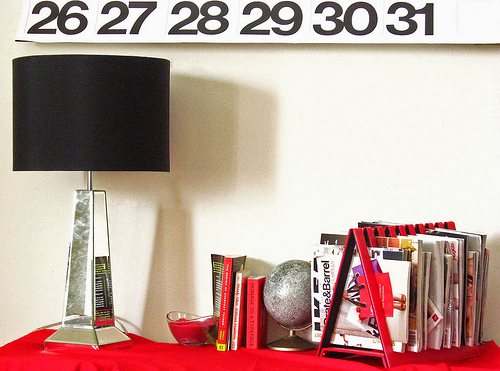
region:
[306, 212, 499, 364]
a rack full of catalogs/magazines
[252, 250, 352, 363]
a globe is in the photo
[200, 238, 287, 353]
books are on the table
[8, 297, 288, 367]
the cloth over the table is red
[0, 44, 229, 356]
the base of the lamp has a reflective surface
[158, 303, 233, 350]
a red candle sits there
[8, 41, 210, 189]
the lamp shade is black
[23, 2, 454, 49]
the numbers 26 thru 31 are at the top of the photo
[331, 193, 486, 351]
the magazine rack is red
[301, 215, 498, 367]
the magazine rack is shaped like a triangle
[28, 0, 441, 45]
numbers on bottom of poster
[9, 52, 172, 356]
black and clear lamp on table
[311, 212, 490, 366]
magazines in a red rack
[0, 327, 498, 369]
red cloth on table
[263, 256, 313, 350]
small globe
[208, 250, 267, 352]
three standing books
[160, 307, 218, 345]
clear bowl with red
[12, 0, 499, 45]
bottom section of a calender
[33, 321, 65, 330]
part of the lamps cord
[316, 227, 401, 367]
triangle shaped end of rack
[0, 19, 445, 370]
a lamp on a table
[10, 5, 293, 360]
lamp with a black shade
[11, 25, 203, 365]
a lamp on a red table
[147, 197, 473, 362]
books on a table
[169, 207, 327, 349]
books standing up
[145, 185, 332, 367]
books in between two statues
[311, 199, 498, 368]
magazines on a rack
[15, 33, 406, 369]
books on a table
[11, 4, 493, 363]
lamp and books on table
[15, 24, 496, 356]
lamp books and magazines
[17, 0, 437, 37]
black numbers above items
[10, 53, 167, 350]
lamp on the table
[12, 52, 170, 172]
black lamp shade on the lamp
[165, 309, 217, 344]
candle on the table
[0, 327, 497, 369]
red cloth on the table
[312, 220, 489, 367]
display of magazines on the table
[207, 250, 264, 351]
three paperback books on the table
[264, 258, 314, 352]
a small globe on the table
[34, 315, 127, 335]
electrical cord of the lamp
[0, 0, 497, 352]
wall behind the table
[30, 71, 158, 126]
black lampshade on lamp.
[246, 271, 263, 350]
red book on table.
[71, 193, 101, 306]
clear base of lamp.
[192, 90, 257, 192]
shadow on the wall.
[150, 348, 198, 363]
red material on surface.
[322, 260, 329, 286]
black writing on magazine.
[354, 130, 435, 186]
blank wall behind magazines.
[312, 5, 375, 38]
black number on white background.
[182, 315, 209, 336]
candle with red wax.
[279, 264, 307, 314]
silver sphere in holder.